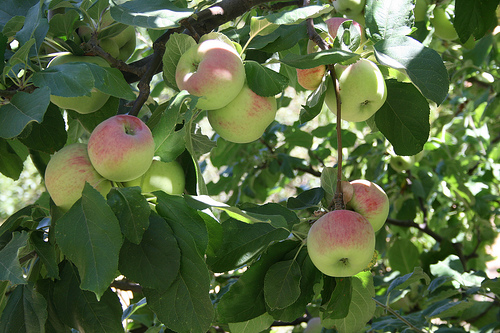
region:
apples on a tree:
[59, 27, 447, 293]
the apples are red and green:
[4, 103, 175, 192]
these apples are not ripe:
[34, 51, 411, 283]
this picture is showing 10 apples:
[54, 27, 421, 291]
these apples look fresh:
[51, 52, 462, 265]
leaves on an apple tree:
[37, 197, 287, 308]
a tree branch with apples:
[52, 20, 302, 122]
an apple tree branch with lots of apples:
[35, 0, 416, 231]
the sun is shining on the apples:
[127, 8, 414, 130]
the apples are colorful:
[45, 36, 390, 268]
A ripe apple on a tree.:
[86, 117, 161, 184]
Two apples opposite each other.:
[159, 37, 287, 152]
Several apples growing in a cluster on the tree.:
[22, 20, 414, 304]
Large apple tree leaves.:
[57, 205, 226, 323]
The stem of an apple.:
[331, 174, 343, 207]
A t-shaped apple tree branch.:
[76, 39, 169, 104]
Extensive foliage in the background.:
[431, 100, 493, 280]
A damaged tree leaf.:
[167, 114, 192, 150]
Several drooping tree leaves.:
[0, 210, 55, 332]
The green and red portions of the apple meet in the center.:
[96, 128, 118, 175]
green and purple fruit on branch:
[311, 211, 376, 276]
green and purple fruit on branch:
[88, 112, 152, 179]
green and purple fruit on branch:
[175, 39, 243, 109]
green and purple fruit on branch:
[321, 49, 383, 126]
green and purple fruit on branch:
[340, 179, 387, 229]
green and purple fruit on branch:
[208, 86, 280, 143]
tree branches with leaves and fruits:
[29, 15, 455, 309]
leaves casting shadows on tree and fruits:
[27, 13, 466, 310]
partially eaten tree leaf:
[55, 179, 128, 307]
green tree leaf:
[32, 58, 96, 103]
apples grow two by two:
[36, 107, 163, 236]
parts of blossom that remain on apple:
[182, 50, 204, 80]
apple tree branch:
[320, 32, 347, 214]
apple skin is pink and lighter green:
[304, 176, 390, 283]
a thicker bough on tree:
[0, 0, 330, 81]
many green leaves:
[5, 3, 300, 329]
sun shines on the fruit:
[167, 13, 422, 103]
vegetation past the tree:
[0, 150, 50, 220]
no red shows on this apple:
[137, 143, 185, 201]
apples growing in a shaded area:
[1, 82, 191, 219]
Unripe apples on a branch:
[307, 177, 388, 281]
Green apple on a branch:
[327, 56, 386, 120]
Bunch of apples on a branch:
[46, 112, 192, 212]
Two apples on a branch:
[178, 35, 277, 141]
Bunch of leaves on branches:
[0, 203, 307, 327]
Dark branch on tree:
[95, 0, 250, 115]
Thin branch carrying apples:
[306, 8, 359, 209]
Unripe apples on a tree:
[45, 17, 397, 280]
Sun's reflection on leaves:
[325, 1, 427, 66]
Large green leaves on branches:
[58, 183, 241, 328]